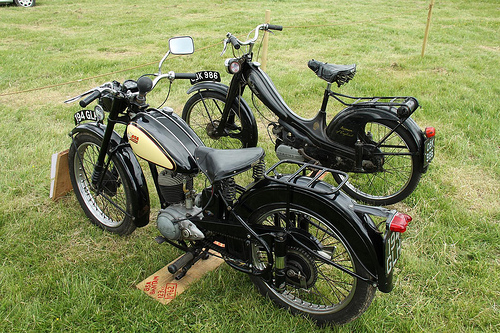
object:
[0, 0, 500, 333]
grass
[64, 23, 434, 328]
bike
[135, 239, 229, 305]
cardboard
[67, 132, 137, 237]
wheel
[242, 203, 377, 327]
wheel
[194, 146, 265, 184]
seat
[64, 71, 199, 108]
handlebars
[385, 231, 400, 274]
plate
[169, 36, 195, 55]
mirror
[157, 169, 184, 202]
engine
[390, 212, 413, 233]
light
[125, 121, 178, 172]
post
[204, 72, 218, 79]
number